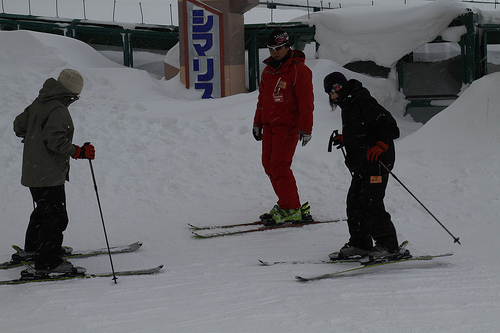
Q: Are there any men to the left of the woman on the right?
A: Yes, there is a man to the left of the woman.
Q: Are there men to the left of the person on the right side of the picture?
A: Yes, there is a man to the left of the woman.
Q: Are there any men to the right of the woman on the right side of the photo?
A: No, the man is to the left of the woman.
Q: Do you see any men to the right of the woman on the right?
A: No, the man is to the left of the woman.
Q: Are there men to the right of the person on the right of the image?
A: No, the man is to the left of the woman.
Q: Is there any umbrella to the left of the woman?
A: No, there is a man to the left of the woman.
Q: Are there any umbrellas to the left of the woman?
A: No, there is a man to the left of the woman.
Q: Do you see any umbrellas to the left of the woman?
A: No, there is a man to the left of the woman.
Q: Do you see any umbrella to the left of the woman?
A: No, there is a man to the left of the woman.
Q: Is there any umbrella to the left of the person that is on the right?
A: No, there is a man to the left of the woman.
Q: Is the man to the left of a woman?
A: Yes, the man is to the left of a woman.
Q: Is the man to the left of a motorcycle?
A: No, the man is to the left of a woman.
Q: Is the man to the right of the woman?
A: No, the man is to the left of the woman.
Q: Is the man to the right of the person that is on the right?
A: No, the man is to the left of the woman.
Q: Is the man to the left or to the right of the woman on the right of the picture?
A: The man is to the left of the woman.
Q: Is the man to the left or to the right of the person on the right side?
A: The man is to the left of the woman.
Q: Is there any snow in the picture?
A: Yes, there is snow.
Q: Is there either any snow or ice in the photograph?
A: Yes, there is snow.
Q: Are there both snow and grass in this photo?
A: No, there is snow but no grass.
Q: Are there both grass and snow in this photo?
A: No, there is snow but no grass.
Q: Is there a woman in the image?
A: Yes, there is a woman.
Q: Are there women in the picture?
A: Yes, there is a woman.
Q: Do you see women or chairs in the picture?
A: Yes, there is a woman.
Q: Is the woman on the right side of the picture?
A: Yes, the woman is on the right of the image.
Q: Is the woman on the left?
A: No, the woman is on the right of the image.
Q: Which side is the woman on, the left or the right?
A: The woman is on the right of the image.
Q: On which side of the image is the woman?
A: The woman is on the right of the image.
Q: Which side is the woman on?
A: The woman is on the right of the image.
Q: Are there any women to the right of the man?
A: Yes, there is a woman to the right of the man.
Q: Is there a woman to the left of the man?
A: No, the woman is to the right of the man.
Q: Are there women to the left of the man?
A: No, the woman is to the right of the man.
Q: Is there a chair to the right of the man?
A: No, there is a woman to the right of the man.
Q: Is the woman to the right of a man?
A: Yes, the woman is to the right of a man.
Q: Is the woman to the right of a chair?
A: No, the woman is to the right of a man.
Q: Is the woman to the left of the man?
A: No, the woman is to the right of the man.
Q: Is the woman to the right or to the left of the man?
A: The woman is to the right of the man.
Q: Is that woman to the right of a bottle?
A: No, the woman is to the right of the ski.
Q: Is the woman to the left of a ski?
A: No, the woman is to the right of a ski.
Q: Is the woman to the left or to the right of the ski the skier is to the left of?
A: The woman is to the right of the ski.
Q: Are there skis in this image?
A: Yes, there are skis.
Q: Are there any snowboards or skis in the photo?
A: Yes, there are skis.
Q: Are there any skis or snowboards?
A: Yes, there are skis.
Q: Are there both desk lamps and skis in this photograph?
A: No, there are skis but no desk lamps.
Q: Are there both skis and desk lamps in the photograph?
A: No, there are skis but no desk lamps.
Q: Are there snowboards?
A: No, there are no snowboards.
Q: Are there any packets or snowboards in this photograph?
A: No, there are no snowboards or packets.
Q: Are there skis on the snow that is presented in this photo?
A: Yes, there are skis on the snow.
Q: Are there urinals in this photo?
A: No, there are no urinals.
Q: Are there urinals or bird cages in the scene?
A: No, there are no urinals or bird cages.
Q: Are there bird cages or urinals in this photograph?
A: No, there are no urinals or bird cages.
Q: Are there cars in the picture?
A: No, there are no cars.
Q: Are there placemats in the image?
A: No, there are no placemats.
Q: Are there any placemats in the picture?
A: No, there are no placemats.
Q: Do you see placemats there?
A: No, there are no placemats.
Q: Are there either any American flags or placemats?
A: No, there are no placemats or American flags.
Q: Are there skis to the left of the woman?
A: Yes, there is a ski to the left of the woman.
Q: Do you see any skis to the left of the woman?
A: Yes, there is a ski to the left of the woman.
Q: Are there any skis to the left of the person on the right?
A: Yes, there is a ski to the left of the woman.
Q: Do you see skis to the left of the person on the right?
A: Yes, there is a ski to the left of the woman.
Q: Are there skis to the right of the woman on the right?
A: No, the ski is to the left of the woman.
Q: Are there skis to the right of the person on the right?
A: No, the ski is to the left of the woman.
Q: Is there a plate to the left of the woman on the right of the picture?
A: No, there is a ski to the left of the woman.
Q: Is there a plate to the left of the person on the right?
A: No, there is a ski to the left of the woman.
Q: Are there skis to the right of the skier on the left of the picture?
A: Yes, there is a ski to the right of the skier.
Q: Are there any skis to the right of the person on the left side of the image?
A: Yes, there is a ski to the right of the skier.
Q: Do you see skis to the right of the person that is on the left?
A: Yes, there is a ski to the right of the skier.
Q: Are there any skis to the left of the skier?
A: No, the ski is to the right of the skier.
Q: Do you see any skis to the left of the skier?
A: No, the ski is to the right of the skier.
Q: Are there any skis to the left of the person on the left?
A: No, the ski is to the right of the skier.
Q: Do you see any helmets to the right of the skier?
A: No, there is a ski to the right of the skier.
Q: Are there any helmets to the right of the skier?
A: No, there is a ski to the right of the skier.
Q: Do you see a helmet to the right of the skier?
A: No, there is a ski to the right of the skier.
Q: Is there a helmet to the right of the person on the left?
A: No, there is a ski to the right of the skier.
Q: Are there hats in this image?
A: Yes, there is a hat.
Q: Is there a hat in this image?
A: Yes, there is a hat.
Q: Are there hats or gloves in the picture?
A: Yes, there is a hat.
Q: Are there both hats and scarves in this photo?
A: No, there is a hat but no scarves.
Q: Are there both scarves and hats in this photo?
A: No, there is a hat but no scarves.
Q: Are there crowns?
A: No, there are no crowns.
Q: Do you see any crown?
A: No, there are no crowns.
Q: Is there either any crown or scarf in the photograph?
A: No, there are no crowns or scarves.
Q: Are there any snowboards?
A: No, there are no snowboards.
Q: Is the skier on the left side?
A: Yes, the skier is on the left of the image.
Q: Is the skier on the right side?
A: No, the skier is on the left of the image.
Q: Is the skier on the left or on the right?
A: The skier is on the left of the image.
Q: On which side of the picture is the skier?
A: The skier is on the left of the image.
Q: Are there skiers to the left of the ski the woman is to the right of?
A: Yes, there is a skier to the left of the ski.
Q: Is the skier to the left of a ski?
A: Yes, the skier is to the left of a ski.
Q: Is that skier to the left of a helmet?
A: No, the skier is to the left of a ski.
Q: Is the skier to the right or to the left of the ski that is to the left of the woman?
A: The skier is to the left of the ski.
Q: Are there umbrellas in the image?
A: No, there are no umbrellas.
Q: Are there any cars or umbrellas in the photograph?
A: No, there are no umbrellas or cars.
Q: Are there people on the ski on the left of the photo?
A: Yes, there are people on the ski.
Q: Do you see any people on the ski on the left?
A: Yes, there are people on the ski.